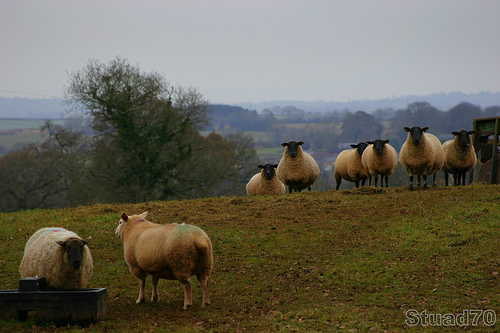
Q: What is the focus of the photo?
A: A herd of sheep.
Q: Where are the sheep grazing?
A: A hilly field.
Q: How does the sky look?
A: Grey and hazy.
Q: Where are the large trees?
A: Other side of hill.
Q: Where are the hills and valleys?
A: Behind the sheep.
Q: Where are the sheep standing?
A: On a grassy hill.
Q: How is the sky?
A: Overcast and gray.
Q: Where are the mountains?
A: In the distance behind the sheep.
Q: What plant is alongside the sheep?
A: A tree.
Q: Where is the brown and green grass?
A: On the ground.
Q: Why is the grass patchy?
A: Because it has been grazed and trampled on.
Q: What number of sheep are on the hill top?
A: 6.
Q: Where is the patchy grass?
A: On the ground.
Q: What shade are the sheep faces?
A: Black.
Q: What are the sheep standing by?
A: Water container.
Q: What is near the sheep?
A: Tree.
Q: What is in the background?
A: Hills.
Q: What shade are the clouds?
A: White.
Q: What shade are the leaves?
A: Green.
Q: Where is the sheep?
A: Field.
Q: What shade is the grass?
A: Green.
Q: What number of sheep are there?
A: Eight.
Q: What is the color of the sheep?
A: White.